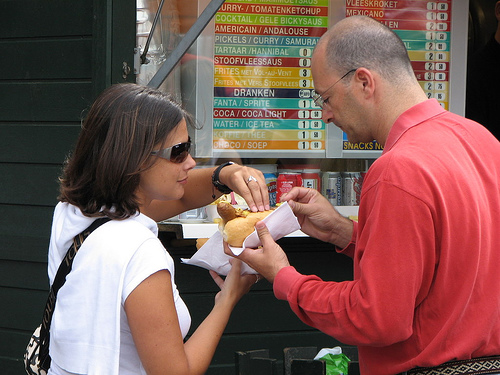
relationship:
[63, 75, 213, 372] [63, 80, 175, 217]
woman has dark hair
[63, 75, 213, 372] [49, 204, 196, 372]
woman has white shirt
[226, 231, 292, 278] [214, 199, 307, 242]
hand holding hot dog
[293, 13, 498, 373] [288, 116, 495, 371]
man has red shirt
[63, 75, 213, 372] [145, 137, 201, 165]
woman has sunglasses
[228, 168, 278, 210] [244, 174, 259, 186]
hand has a ring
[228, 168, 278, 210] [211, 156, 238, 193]
hand has a watch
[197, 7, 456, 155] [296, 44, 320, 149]
sign has price(s)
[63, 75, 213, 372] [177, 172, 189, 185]
woman has a mouth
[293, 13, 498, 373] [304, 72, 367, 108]
man has glasses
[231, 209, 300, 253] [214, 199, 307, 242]
napkin containing hot dog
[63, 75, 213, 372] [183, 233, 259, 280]
woman holding white napkin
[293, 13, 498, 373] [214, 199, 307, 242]
man has a hot dog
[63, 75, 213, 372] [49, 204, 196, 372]
woman has a white shirt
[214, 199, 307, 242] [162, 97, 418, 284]
hot dog about to be eaten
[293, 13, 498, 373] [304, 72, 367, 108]
man has on glasses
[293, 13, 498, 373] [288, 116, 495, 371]
man has on a red shirt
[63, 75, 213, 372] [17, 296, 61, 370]
woman has purse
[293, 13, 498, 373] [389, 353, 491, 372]
man has diamond style belt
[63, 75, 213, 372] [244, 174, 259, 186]
woman has ring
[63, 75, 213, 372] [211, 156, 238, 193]
woman has watch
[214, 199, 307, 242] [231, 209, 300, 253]
hot dog on white paper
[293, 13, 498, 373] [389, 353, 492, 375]
man has a diamond style belt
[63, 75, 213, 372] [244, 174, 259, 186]
woman has a ring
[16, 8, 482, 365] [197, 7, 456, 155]
place has menu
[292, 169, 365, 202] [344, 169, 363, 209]
beer in soda can